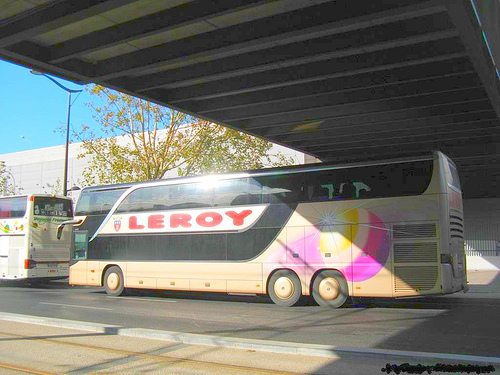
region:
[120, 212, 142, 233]
a letter on the bus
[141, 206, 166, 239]
a letter on the bus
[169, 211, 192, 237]
a letter on the bus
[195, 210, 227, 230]
a letter on the bus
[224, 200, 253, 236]
a letter on the bus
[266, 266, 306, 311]
this is a wheel of a bus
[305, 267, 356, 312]
this is a wheel of a bus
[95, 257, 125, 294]
this is a wheel of a bus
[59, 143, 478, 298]
this is a bus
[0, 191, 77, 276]
this is a bus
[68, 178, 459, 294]
a bus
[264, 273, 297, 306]
tires on the bus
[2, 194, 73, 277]
a white bus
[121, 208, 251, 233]
logo on the bus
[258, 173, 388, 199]
windows on the bus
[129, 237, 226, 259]
windows on the bottom of the bus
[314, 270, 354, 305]
the back tire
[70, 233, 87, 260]
a door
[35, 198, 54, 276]
back of the bus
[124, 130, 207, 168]
the tree branches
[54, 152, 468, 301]
a white and black tour bus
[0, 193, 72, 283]
a white tour bus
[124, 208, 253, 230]
LEROY company name in red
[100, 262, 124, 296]
front left bus tire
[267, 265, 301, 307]
rear left bus tire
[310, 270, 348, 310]
rear left bus tire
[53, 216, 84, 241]
bus rear view mirror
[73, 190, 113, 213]
large bus passenger window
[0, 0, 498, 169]
bottom of bridge overpass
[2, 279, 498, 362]
a grey paved street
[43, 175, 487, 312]
A bus on the street.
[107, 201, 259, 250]
The name Leroy on the bus.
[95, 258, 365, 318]
The tires on the bus.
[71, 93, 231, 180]
A tree behind the bus.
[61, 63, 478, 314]
The bus is under the freeway.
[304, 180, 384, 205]
People on the bus.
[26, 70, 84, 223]
A light pole by the building.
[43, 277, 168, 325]
The street has white line in middle.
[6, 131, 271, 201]
A building by the freeway.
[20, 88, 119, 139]
The sky is clear.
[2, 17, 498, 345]
buses under the bridge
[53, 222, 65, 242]
a side mirror of the bus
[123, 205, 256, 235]
a word LEROY printed on the bus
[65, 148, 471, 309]
a double decker bus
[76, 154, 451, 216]
the upper deck of the bus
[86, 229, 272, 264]
windows of the lower deck of the bus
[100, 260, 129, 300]
the front wheel of the double decker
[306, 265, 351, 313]
the back wheel of the double decker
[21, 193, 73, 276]
a back of a double decker bus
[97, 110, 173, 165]
trees with yellow and green leaves